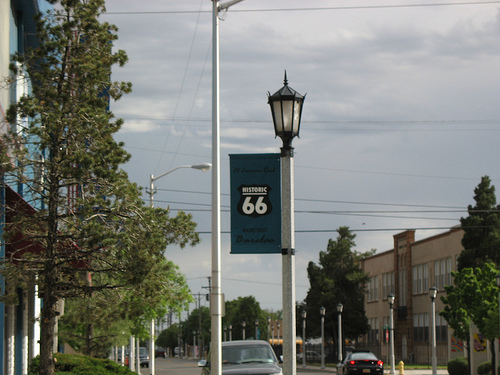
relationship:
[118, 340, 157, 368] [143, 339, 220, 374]
car in street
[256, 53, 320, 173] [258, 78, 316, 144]
lamps with glass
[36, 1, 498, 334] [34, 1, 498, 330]
cloud cover with sky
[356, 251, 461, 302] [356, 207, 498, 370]
windows of building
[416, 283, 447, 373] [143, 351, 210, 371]
streetlamp on street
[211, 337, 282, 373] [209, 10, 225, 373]
car parked beside pole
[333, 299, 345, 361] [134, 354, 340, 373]
lamppost on street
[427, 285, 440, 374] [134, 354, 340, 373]
lamppost on street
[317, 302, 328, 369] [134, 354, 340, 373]
lamppost on street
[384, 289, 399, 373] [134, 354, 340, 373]
lamppost on street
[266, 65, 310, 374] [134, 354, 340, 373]
lamppost on street